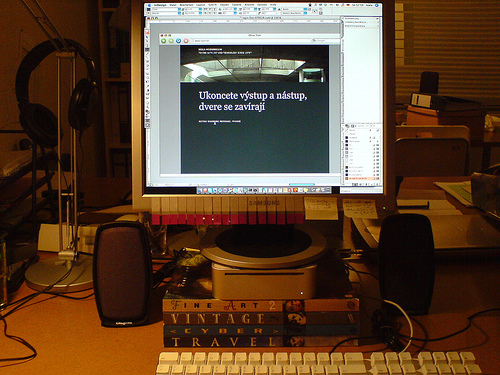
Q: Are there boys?
A: No, there are no boys.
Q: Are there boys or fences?
A: No, there are no boys or fences.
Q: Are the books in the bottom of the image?
A: Yes, the books are in the bottom of the image.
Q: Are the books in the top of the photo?
A: No, the books are in the bottom of the image.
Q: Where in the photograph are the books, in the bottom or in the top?
A: The books are in the bottom of the image.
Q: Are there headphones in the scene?
A: Yes, there are headphones.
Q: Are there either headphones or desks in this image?
A: Yes, there are headphones.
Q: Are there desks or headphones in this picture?
A: Yes, there are headphones.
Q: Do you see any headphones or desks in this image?
A: Yes, there are headphones.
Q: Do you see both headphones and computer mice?
A: No, there are headphones but no computer mice.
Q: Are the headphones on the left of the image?
A: Yes, the headphones are on the left of the image.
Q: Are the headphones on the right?
A: No, the headphones are on the left of the image.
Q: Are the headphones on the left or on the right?
A: The headphones are on the left of the image.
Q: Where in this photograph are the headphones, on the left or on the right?
A: The headphones are on the left of the image.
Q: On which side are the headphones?
A: The headphones are on the left of the image.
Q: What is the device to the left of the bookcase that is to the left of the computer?
A: The device is headphones.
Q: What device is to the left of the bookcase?
A: The device is headphones.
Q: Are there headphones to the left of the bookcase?
A: Yes, there are headphones to the left of the bookcase.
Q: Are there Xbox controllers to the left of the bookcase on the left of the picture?
A: No, there are headphones to the left of the bookcase.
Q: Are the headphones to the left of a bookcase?
A: Yes, the headphones are to the left of a bookcase.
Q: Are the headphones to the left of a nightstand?
A: No, the headphones are to the left of a bookcase.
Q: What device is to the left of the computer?
A: The device is headphones.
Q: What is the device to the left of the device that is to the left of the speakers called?
A: The device is headphones.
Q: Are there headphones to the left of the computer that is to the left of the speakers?
A: Yes, there are headphones to the left of the computer.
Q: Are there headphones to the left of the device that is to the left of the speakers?
A: Yes, there are headphones to the left of the computer.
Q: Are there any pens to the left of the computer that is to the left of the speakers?
A: No, there are headphones to the left of the computer.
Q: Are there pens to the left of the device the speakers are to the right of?
A: No, there are headphones to the left of the computer.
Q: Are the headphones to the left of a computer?
A: Yes, the headphones are to the left of a computer.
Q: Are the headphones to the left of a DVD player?
A: No, the headphones are to the left of a computer.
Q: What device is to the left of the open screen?
A: The device is headphones.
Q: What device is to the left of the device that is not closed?
A: The device is headphones.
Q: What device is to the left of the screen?
A: The device is headphones.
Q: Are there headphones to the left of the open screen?
A: Yes, there are headphones to the left of the screen.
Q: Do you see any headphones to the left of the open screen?
A: Yes, there are headphones to the left of the screen.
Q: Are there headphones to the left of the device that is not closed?
A: Yes, there are headphones to the left of the screen.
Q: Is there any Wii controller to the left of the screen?
A: No, there are headphones to the left of the screen.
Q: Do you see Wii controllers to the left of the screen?
A: No, there are headphones to the left of the screen.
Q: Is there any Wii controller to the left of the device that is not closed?
A: No, there are headphones to the left of the screen.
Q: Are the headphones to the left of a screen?
A: Yes, the headphones are to the left of a screen.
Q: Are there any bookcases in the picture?
A: Yes, there is a bookcase.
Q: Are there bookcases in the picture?
A: Yes, there is a bookcase.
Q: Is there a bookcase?
A: Yes, there is a bookcase.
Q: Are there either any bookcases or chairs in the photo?
A: Yes, there is a bookcase.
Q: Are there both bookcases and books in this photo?
A: Yes, there are both a bookcase and a book.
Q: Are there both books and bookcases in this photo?
A: Yes, there are both a bookcase and a book.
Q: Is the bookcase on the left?
A: Yes, the bookcase is on the left of the image.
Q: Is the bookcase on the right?
A: No, the bookcase is on the left of the image.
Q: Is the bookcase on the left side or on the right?
A: The bookcase is on the left of the image.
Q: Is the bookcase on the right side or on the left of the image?
A: The bookcase is on the left of the image.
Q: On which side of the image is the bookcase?
A: The bookcase is on the left of the image.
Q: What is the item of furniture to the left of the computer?
A: The piece of furniture is a bookcase.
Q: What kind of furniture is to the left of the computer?
A: The piece of furniture is a bookcase.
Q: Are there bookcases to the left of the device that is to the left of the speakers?
A: Yes, there is a bookcase to the left of the computer.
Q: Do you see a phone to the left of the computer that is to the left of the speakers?
A: No, there is a bookcase to the left of the computer.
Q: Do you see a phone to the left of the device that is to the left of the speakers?
A: No, there is a bookcase to the left of the computer.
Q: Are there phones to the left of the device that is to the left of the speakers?
A: No, there is a bookcase to the left of the computer.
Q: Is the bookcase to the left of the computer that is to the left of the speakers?
A: Yes, the bookcase is to the left of the computer.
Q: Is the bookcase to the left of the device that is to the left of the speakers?
A: Yes, the bookcase is to the left of the computer.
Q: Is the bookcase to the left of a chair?
A: No, the bookcase is to the left of the computer.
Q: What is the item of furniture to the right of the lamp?
A: The piece of furniture is a bookcase.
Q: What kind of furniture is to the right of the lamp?
A: The piece of furniture is a bookcase.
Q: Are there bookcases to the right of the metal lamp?
A: Yes, there is a bookcase to the right of the lamp.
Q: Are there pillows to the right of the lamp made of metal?
A: No, there is a bookcase to the right of the lamp.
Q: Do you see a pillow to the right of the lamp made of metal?
A: No, there is a bookcase to the right of the lamp.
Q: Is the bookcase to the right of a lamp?
A: Yes, the bookcase is to the right of a lamp.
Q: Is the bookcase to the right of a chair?
A: No, the bookcase is to the right of a lamp.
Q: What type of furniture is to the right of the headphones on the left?
A: The piece of furniture is a bookcase.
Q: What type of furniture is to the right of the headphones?
A: The piece of furniture is a bookcase.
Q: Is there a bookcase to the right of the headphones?
A: Yes, there is a bookcase to the right of the headphones.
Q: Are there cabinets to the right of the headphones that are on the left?
A: No, there is a bookcase to the right of the headphones.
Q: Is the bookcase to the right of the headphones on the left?
A: Yes, the bookcase is to the right of the headphones.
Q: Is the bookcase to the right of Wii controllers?
A: No, the bookcase is to the right of the headphones.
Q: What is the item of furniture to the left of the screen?
A: The piece of furniture is a bookcase.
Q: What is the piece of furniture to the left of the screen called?
A: The piece of furniture is a bookcase.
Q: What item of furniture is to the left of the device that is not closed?
A: The piece of furniture is a bookcase.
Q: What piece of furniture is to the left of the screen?
A: The piece of furniture is a bookcase.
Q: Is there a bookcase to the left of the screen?
A: Yes, there is a bookcase to the left of the screen.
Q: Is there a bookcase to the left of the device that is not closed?
A: Yes, there is a bookcase to the left of the screen.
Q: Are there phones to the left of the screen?
A: No, there is a bookcase to the left of the screen.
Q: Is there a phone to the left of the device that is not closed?
A: No, there is a bookcase to the left of the screen.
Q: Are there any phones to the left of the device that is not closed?
A: No, there is a bookcase to the left of the screen.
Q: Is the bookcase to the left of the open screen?
A: Yes, the bookcase is to the left of the screen.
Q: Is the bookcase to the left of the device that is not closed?
A: Yes, the bookcase is to the left of the screen.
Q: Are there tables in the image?
A: Yes, there is a table.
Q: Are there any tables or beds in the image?
A: Yes, there is a table.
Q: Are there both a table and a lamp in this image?
A: Yes, there are both a table and a lamp.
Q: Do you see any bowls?
A: No, there are no bowls.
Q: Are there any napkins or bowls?
A: No, there are no bowls or napkins.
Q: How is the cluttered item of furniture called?
A: The piece of furniture is a table.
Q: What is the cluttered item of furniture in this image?
A: The piece of furniture is a table.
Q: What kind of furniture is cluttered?
A: The furniture is a table.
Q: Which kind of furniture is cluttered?
A: The furniture is a table.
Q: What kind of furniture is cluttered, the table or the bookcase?
A: The table is cluttered.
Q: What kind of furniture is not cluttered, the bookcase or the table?
A: The bookcase is not cluttered.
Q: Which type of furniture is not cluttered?
A: The furniture is a bookcase.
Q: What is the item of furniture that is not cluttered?
A: The piece of furniture is a bookcase.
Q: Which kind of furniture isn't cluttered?
A: The furniture is a bookcase.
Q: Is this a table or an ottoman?
A: This is a table.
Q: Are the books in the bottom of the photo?
A: Yes, the books are in the bottom of the image.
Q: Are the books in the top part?
A: No, the books are in the bottom of the image.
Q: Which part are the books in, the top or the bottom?
A: The books are in the bottom of the image.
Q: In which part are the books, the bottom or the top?
A: The books are in the bottom of the image.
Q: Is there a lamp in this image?
A: Yes, there is a lamp.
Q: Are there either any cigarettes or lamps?
A: Yes, there is a lamp.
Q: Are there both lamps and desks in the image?
A: Yes, there are both a lamp and a desk.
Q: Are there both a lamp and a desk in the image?
A: Yes, there are both a lamp and a desk.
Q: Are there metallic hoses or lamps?
A: Yes, there is a metal lamp.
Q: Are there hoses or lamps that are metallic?
A: Yes, the lamp is metallic.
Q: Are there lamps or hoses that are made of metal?
A: Yes, the lamp is made of metal.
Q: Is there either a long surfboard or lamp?
A: Yes, there is a long lamp.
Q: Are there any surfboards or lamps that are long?
A: Yes, the lamp is long.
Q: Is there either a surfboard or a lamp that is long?
A: Yes, the lamp is long.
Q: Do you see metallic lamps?
A: Yes, there is a metal lamp.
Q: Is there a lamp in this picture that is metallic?
A: Yes, there is a lamp that is metallic.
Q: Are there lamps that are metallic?
A: Yes, there is a lamp that is metallic.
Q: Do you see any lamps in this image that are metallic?
A: Yes, there is a lamp that is metallic.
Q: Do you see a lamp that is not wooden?
A: Yes, there is a metallic lamp.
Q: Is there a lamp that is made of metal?
A: Yes, there is a lamp that is made of metal.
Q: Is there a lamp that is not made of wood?
A: Yes, there is a lamp that is made of metal.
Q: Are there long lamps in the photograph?
A: Yes, there is a long lamp.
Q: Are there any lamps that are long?
A: Yes, there is a lamp that is long.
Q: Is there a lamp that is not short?
A: Yes, there is a long lamp.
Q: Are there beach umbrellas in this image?
A: No, there are no beach umbrellas.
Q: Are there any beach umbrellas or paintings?
A: No, there are no beach umbrellas or paintings.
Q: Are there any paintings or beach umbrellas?
A: No, there are no beach umbrellas or paintings.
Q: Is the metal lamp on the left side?
A: Yes, the lamp is on the left of the image.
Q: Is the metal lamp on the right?
A: No, the lamp is on the left of the image.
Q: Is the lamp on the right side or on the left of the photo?
A: The lamp is on the left of the image.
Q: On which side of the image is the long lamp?
A: The lamp is on the left of the image.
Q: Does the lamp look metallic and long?
A: Yes, the lamp is metallic and long.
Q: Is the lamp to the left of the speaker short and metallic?
A: No, the lamp is metallic but long.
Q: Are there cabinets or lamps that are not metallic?
A: No, there is a lamp but it is metallic.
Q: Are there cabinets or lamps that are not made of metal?
A: No, there is a lamp but it is made of metal.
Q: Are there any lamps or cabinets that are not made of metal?
A: No, there is a lamp but it is made of metal.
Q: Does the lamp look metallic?
A: Yes, the lamp is metallic.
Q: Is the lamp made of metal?
A: Yes, the lamp is made of metal.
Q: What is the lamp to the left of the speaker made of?
A: The lamp is made of metal.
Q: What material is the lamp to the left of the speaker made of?
A: The lamp is made of metal.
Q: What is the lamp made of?
A: The lamp is made of metal.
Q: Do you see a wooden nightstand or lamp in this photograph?
A: No, there is a lamp but it is metallic.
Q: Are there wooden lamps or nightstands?
A: No, there is a lamp but it is metallic.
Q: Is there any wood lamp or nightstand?
A: No, there is a lamp but it is metallic.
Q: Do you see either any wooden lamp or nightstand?
A: No, there is a lamp but it is metallic.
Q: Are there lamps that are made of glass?
A: No, there is a lamp but it is made of metal.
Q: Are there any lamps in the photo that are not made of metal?
A: No, there is a lamp but it is made of metal.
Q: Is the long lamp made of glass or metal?
A: The lamp is made of metal.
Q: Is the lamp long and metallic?
A: Yes, the lamp is long and metallic.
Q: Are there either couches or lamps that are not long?
A: No, there is a lamp but it is long.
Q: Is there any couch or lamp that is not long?
A: No, there is a lamp but it is long.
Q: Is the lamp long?
A: Yes, the lamp is long.